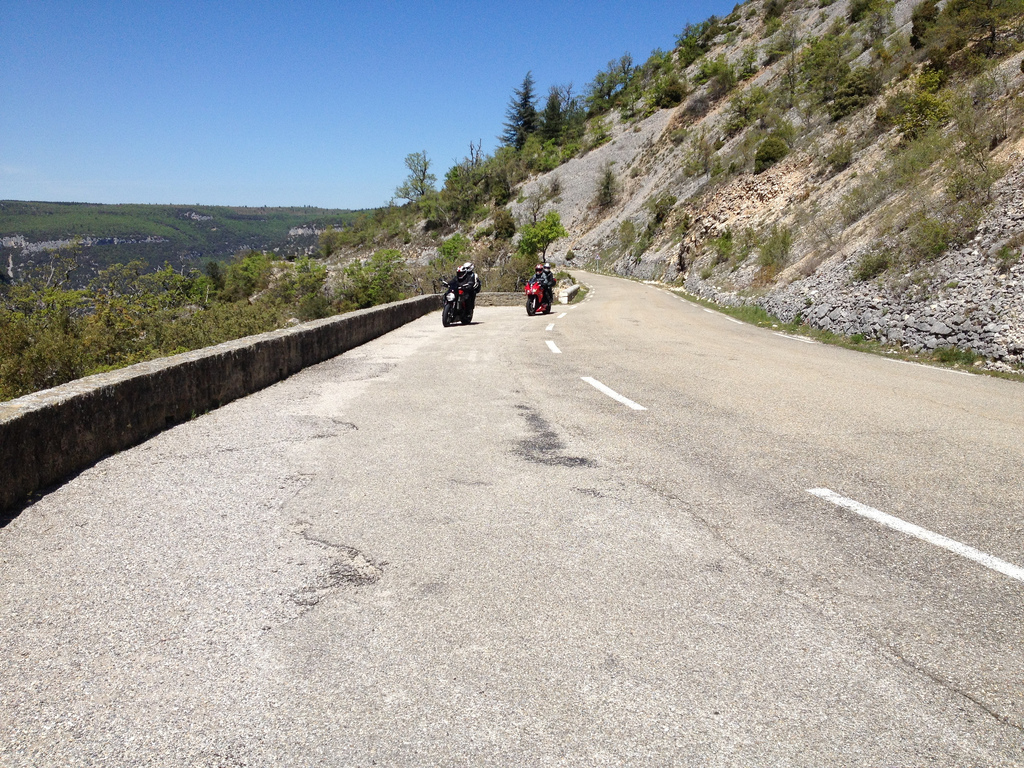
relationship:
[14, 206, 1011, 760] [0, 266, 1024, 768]
asphalt on asphalt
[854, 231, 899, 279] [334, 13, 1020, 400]
bush growing on side of mountain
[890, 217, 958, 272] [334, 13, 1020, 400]
bush growing on mountain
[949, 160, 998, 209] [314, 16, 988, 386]
bush growing on mountain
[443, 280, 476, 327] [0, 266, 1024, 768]
motorcycle on asphalt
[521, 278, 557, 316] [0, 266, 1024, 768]
motorcycle on asphalt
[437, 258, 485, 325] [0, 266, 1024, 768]
motorcycle on asphalt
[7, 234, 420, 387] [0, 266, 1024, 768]
plants by asphalt